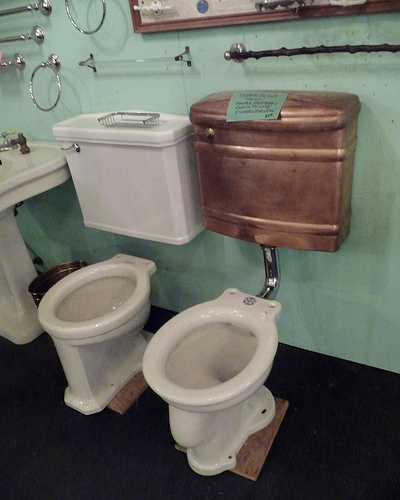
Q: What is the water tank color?
A: Gold.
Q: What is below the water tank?
A: Toilet bowl.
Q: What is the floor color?
A: Black.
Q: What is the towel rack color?
A: Black.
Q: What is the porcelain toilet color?
A: White.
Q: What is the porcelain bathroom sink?
A: White.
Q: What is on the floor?
A: The commode.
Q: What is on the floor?
A: The commode.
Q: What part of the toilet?
A: The tank.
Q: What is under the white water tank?
A: The toilet.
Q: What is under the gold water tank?
A: The toilet.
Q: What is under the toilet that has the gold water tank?
A: Piece of wood.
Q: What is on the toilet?
A: The white lid.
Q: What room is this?
A: The bathroom.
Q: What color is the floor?
A: Black.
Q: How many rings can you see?
A: Two.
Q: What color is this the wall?
A: The wall is blue.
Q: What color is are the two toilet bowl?
A: There are white.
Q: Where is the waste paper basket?
A: Next to the sink.